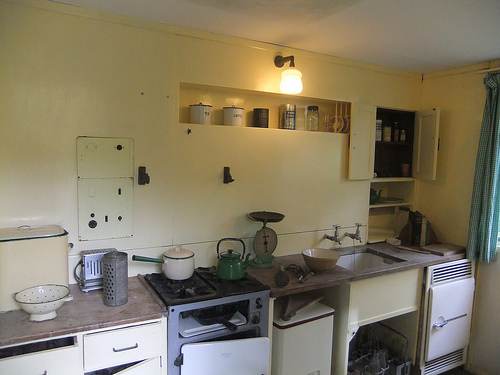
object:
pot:
[132, 245, 194, 280]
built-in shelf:
[179, 81, 352, 134]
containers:
[189, 102, 212, 124]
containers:
[223, 105, 245, 127]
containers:
[253, 107, 269, 128]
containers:
[280, 103, 297, 130]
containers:
[304, 106, 318, 132]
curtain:
[466, 74, 500, 264]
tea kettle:
[216, 238, 251, 281]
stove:
[145, 265, 273, 375]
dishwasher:
[346, 270, 419, 375]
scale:
[246, 211, 285, 268]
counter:
[242, 253, 353, 297]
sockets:
[77, 135, 136, 242]